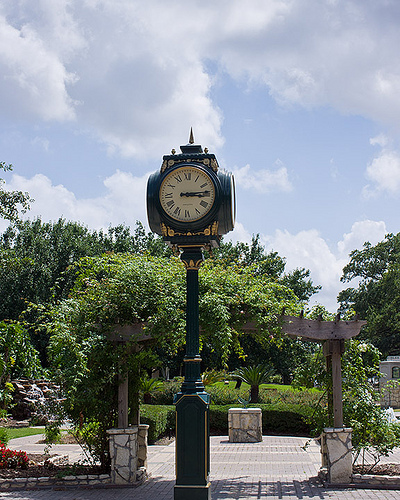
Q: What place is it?
A: It is a garden.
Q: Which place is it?
A: It is a garden.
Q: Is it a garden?
A: Yes, it is a garden.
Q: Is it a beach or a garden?
A: It is a garden.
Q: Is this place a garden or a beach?
A: It is a garden.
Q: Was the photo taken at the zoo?
A: No, the picture was taken in the garden.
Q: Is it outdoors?
A: Yes, it is outdoors.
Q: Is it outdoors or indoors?
A: It is outdoors.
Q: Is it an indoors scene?
A: No, it is outdoors.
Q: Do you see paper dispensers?
A: No, there are no paper dispensers.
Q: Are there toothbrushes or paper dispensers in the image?
A: No, there are no paper dispensers or toothbrushes.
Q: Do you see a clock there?
A: Yes, there is a clock.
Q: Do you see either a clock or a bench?
A: Yes, there is a clock.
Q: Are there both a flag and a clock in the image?
A: No, there is a clock but no flags.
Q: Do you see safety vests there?
A: No, there are no safety vests.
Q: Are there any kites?
A: No, there are no kites.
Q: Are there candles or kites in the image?
A: No, there are no kites or candles.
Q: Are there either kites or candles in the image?
A: No, there are no kites or candles.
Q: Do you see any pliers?
A: No, there are no pliers.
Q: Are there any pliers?
A: No, there are no pliers.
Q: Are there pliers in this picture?
A: No, there are no pliers.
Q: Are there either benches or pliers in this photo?
A: No, there are no pliers or benches.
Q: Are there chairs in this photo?
A: No, there are no chairs.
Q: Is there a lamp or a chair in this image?
A: No, there are no chairs or lamps.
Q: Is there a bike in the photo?
A: No, there are no bikes.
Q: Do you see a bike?
A: No, there are no bikes.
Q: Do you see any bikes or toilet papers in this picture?
A: No, there are no bikes or toilet papers.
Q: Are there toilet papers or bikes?
A: No, there are no bikes or toilet papers.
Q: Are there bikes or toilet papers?
A: No, there are no bikes or toilet papers.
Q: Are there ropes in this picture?
A: No, there are no ropes.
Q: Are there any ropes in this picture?
A: No, there are no ropes.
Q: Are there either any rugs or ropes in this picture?
A: No, there are no ropes or rugs.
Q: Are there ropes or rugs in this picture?
A: No, there are no ropes or rugs.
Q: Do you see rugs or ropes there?
A: No, there are no ropes or rugs.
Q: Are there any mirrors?
A: No, there are no mirrors.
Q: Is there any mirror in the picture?
A: No, there are no mirrors.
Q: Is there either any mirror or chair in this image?
A: No, there are no mirrors or chairs.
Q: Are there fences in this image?
A: No, there are no fences.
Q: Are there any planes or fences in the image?
A: No, there are no fences or planes.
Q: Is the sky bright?
A: Yes, the sky is bright.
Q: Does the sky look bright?
A: Yes, the sky is bright.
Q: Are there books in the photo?
A: No, there are no books.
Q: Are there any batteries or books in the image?
A: No, there are no books or batteries.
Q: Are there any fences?
A: No, there are no fences.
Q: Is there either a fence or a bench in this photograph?
A: No, there are no fences or benches.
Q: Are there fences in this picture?
A: No, there are no fences.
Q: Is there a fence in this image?
A: No, there are no fences.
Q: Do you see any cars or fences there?
A: No, there are no fences or cars.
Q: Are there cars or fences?
A: No, there are no fences or cars.